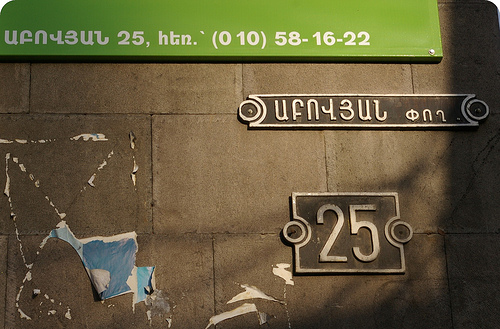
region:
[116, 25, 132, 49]
The number is white.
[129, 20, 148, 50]
The number is white.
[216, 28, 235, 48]
The number is white.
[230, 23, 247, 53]
The number is white.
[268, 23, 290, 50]
The number is white.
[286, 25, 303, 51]
The number is white.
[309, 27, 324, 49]
The number is white.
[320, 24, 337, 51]
The number is white.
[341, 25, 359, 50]
The number is white.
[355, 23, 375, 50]
The number is white.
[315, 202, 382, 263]
A grey number 25 that is large in size.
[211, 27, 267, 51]
(010) on a green sign.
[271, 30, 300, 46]
White 58 before a -.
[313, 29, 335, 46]
White number 16.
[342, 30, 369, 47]
A white number 22.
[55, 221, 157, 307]
A ripped blue and white piece of paper on the wall.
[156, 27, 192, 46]
The letters htn.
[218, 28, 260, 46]
An 0 10 in parenthesis.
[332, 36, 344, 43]
The small white - between 16 and 22.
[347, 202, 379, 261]
A large grey number 5 next to a 2.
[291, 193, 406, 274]
White and black sign with the number 25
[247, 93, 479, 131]
Long black and white sign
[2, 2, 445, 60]
Large long green sign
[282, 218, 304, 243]
Small black and white circle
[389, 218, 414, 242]
Small white and black circle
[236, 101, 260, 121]
Black and white small circle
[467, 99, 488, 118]
Small black and white circle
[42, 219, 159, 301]
Ripped blue torn area wall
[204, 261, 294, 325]
Ripped up white wall area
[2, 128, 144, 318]
Ripped up white and grey wall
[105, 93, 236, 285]
grey cement block wall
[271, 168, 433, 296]
black and silver plate on the wall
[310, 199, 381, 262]
the number 25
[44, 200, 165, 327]
remnants of a poster on the wall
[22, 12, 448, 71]
green sign on the wall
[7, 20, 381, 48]
white writing on the green sign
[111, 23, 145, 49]
the number 25 on the green sign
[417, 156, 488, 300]
shadow on the wall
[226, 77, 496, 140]
black and silver retangular sign on the wall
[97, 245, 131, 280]
blue poster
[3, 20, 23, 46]
White letter on green sign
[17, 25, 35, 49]
White letter on green sign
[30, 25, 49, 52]
White letter on green sign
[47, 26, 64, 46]
White letter on green sign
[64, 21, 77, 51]
White letter on green sign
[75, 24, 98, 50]
White letter on green sign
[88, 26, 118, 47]
White letter on green sign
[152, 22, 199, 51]
White letter on green sign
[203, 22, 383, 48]
White letter on green sign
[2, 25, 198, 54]
White letter on green sign